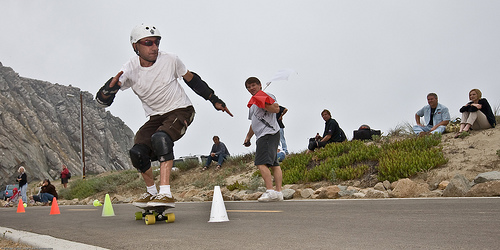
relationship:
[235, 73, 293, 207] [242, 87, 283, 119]
man holding flag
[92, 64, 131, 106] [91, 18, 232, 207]
arm on man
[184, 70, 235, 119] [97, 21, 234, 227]
arm of man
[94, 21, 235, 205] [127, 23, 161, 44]
he has helmet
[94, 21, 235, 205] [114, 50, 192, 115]
he has shirt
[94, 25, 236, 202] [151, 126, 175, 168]
he wearing knee cap